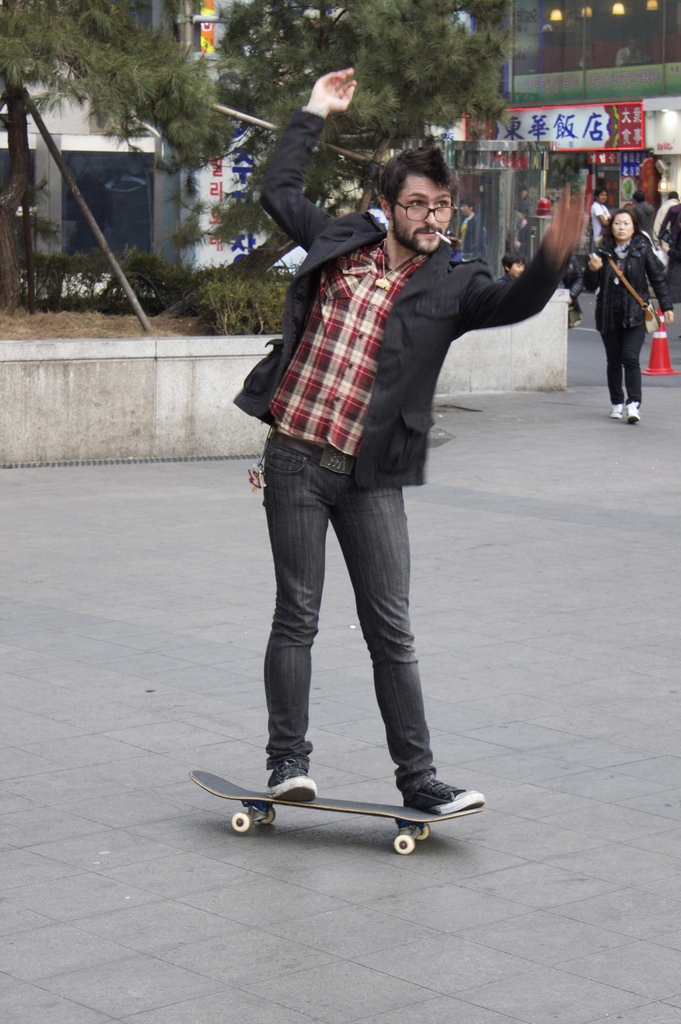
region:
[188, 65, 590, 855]
Young man riding skateboard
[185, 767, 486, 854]
Black skateboard with white wheels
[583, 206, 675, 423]
Asian woman in black jacket and white shoes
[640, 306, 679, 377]
Orange and white traffic cone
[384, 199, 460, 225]
Black eyeglasses on face of skateboarder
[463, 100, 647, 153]
Red, white, and blue sign with Asian text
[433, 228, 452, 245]
Cigarette in skateboarder's mouth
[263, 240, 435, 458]
Red, brown and white plaid shirt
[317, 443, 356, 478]
Large rectangular belt buckle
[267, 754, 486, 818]
Black and white tennis shoes on skateboarder's feet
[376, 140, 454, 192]
Man has dark hair.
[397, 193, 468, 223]
Man wearing glasses on face.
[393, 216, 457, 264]
Man has dark facial hair.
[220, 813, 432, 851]
White wheels on skateboard.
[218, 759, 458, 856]
Man standing on skateboard.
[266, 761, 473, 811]
Man wearing black and white tennis shoes.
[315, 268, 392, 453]
Man wearing plaid shirt.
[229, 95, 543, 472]
Man wearing dark jacket.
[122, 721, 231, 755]
gray stone is tile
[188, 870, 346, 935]
gray stone is tile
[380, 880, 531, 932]
gray stone is tile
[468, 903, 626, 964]
gray stone is tile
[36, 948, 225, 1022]
gray stone is tile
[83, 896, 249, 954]
gray stone is tile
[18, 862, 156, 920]
gray stone is tile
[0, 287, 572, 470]
large grey concrete planting box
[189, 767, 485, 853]
wooden skateboard with a black textured top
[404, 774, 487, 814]
black and white skater shoe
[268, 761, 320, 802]
black and white skater shoe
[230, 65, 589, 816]
man riding on a skateboard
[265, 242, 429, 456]
red and white plaid shirt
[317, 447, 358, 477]
square bronze belt buckle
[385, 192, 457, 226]
black thin framed glasses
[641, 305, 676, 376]
orange and white traffic cone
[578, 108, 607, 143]
A letter on a sign.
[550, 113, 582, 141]
A letter on a sign.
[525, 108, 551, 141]
A letter on a sign.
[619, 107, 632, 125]
A letter on a sign.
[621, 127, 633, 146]
A letter on a sign.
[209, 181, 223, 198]
A letter on a sign.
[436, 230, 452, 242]
cigarette hanging from man's lip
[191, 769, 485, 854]
skateboard being ridden by man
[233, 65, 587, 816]
man riding on skateboard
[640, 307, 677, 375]
orange and white striped cone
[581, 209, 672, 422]
woman wearing white sneakers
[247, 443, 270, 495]
keychain hanging from man's hip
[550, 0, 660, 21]
four lights behind glass window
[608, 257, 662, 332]
brown purse worn by woman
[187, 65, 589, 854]
man on skateboard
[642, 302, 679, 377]
orange and white cone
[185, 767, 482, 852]
black skateboard with white wheels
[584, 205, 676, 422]
woman walking around corner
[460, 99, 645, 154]
sign sign with blue lettering and other part is red with white letters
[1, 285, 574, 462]
retaining wall at edge of street